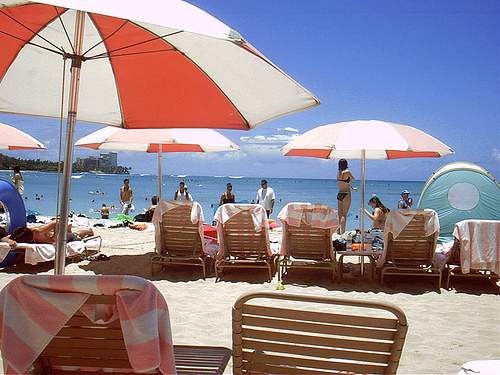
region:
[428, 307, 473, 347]
Part of the sand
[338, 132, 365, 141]
Part of the umbrella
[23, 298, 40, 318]
Part of the towel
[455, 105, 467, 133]
Part of the blue sky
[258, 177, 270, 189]
The head of the person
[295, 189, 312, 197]
Part of the water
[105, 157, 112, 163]
Part of the building in distance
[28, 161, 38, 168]
Part of the green trees in distance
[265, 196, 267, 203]
Part of the white shirt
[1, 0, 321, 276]
A beach umbrella with a white and orange top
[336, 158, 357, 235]
A woman wearing a black two-piece bikini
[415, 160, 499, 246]
A light blue beach tent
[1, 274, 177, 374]
A beach towel with white and light orange strips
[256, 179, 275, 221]
A man wearing a white shirt on the beach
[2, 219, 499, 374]
A beach with white sand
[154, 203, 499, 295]
A row of five beach chairs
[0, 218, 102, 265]
A person laying on a beach chair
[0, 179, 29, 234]
A blue beach tent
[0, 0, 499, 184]
Mostly clear blue sky with random clouds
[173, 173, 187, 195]
head of a person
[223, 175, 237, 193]
head of a person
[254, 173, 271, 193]
head of a person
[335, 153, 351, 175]
head of a person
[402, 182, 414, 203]
head of a person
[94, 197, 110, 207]
head of a person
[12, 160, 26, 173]
head of a person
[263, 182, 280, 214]
arm of a person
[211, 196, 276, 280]
pink and white towel on chair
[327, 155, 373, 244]
woman wearing a black bikini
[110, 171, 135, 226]
man wearing no shirt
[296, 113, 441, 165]
large red and white umbrella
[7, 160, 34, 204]
woman with towel wrapped around her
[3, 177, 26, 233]
large blue tube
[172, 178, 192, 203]
man wearing white tank top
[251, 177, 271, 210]
man wearing white shirt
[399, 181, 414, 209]
man wearing blue baseball cap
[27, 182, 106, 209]
people swimming in the water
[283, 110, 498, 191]
a red and white umbrella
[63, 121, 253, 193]
a white and red umbrella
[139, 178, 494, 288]
tan beach chairs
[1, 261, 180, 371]
a white and pink beach towel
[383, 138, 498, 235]
a blue and white beach tent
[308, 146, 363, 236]
a woman wearing a black bikini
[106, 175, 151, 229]
a man wearing no shirt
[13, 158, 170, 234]
people swimming in the ocean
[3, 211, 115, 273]
a person laying on a beach chair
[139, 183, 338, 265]
pink and white beach towels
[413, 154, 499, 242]
Blue and white tent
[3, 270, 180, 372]
Towel on a chair